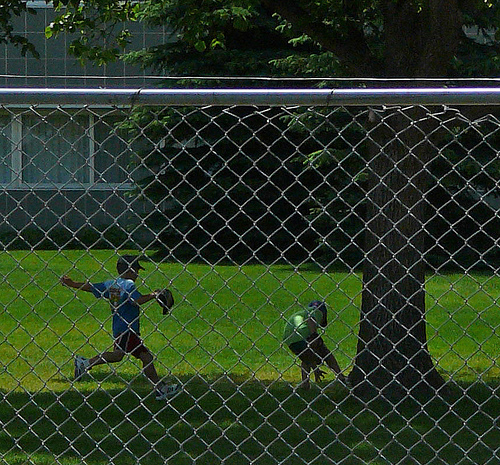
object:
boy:
[57, 243, 187, 400]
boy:
[280, 290, 350, 394]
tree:
[150, 0, 465, 390]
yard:
[0, 229, 500, 464]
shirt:
[282, 308, 322, 345]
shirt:
[86, 278, 143, 334]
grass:
[0, 249, 493, 464]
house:
[1, 0, 266, 244]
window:
[15, 105, 159, 184]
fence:
[1, 77, 498, 464]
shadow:
[0, 373, 499, 464]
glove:
[154, 287, 176, 317]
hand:
[152, 286, 166, 303]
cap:
[113, 252, 148, 273]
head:
[113, 252, 146, 281]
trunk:
[343, 75, 452, 391]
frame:
[1, 180, 144, 195]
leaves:
[24, 41, 47, 60]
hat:
[309, 299, 329, 328]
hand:
[311, 367, 330, 384]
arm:
[58, 272, 110, 296]